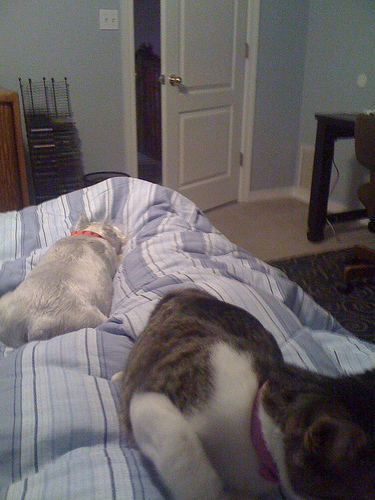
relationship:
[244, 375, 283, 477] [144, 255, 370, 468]
collar on cat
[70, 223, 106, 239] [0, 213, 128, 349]
collar on cat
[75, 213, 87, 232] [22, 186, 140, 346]
ear on cat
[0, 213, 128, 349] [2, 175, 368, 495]
cat lying on bed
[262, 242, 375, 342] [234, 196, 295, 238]
rug on floor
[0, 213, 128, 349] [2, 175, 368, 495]
cat laying on bed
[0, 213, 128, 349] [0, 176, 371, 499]
cat sleeping on blanket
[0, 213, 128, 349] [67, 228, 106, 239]
cat with collar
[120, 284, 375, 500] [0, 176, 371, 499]
cat laying on blanket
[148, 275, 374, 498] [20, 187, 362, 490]
cat sleeping on bed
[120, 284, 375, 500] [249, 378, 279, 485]
cat with collar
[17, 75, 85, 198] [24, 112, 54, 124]
rack of cd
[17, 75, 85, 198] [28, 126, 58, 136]
rack of cd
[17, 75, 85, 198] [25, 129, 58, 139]
rack of cd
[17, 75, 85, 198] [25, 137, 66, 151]
rack of cd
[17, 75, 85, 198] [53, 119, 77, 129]
rack of cd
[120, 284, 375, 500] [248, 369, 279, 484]
cat with collar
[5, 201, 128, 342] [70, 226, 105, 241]
cat with collar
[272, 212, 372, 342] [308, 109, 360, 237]
rug under chair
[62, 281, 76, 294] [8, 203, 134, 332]
fur on cat